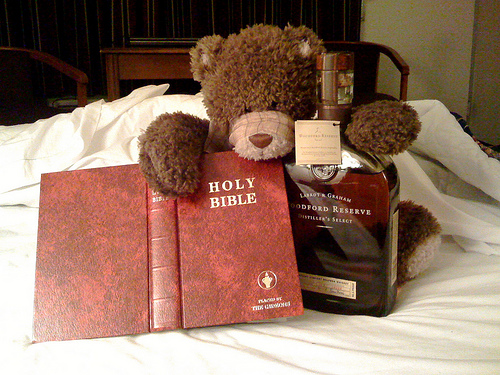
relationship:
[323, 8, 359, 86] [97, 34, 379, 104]
curtains behind table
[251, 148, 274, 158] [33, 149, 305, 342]
mouth on bible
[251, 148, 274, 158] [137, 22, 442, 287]
mouth of bear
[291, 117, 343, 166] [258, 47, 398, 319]
label on bottle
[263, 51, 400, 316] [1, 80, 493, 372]
alcohol on bed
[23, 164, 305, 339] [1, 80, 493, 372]
bible on bed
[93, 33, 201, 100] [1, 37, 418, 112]
table and chairs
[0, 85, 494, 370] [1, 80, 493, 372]
bed sheet on bed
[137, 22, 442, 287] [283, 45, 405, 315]
bear visible through alcohol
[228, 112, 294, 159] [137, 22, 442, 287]
nose of bear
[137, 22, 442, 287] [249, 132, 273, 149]
bear has nose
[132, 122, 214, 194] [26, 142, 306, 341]
paw on bible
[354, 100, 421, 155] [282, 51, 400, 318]
paw on alcohol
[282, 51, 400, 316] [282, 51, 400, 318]
bottle of alcohol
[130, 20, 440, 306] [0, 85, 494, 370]
bear on bed sheet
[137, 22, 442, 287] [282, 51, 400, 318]
bear holding alcohol